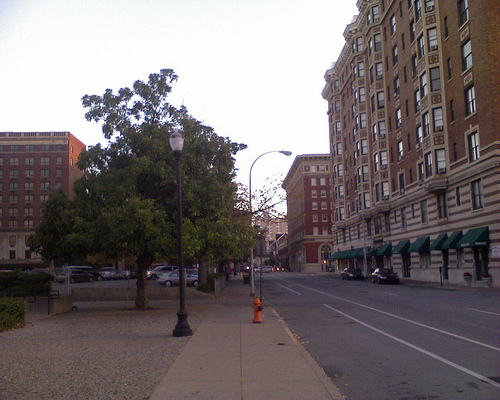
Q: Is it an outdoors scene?
A: Yes, it is outdoors.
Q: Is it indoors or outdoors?
A: It is outdoors.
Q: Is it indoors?
A: No, it is outdoors.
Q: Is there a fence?
A: No, there are no fences.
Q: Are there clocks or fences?
A: No, there are no fences or clocks.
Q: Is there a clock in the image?
A: No, there are no clocks.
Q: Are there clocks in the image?
A: No, there are no clocks.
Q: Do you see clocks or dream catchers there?
A: No, there are no clocks or dream catchers.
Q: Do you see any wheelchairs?
A: No, there are no wheelchairs.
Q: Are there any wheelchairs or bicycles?
A: No, there are no wheelchairs or bicycles.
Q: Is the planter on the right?
A: Yes, the planter is on the right of the image.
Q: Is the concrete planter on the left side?
A: No, the planter is on the right of the image.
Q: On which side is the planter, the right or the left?
A: The planter is on the right of the image.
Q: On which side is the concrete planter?
A: The planter is on the right of the image.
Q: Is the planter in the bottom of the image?
A: Yes, the planter is in the bottom of the image.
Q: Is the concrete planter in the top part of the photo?
A: No, the planter is in the bottom of the image.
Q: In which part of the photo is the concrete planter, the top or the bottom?
A: The planter is in the bottom of the image.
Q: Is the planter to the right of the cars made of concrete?
A: Yes, the planter is made of concrete.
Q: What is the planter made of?
A: The planter is made of concrete.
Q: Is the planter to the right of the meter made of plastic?
A: No, the planter is made of cement.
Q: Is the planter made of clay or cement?
A: The planter is made of cement.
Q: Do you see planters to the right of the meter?
A: Yes, there is a planter to the right of the meter.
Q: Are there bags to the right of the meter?
A: No, there is a planter to the right of the meter.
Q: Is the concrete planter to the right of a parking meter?
A: Yes, the planter is to the right of a parking meter.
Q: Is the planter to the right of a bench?
A: No, the planter is to the right of a parking meter.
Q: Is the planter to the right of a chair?
A: No, the planter is to the right of the car.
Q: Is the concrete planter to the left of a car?
A: No, the planter is to the right of a car.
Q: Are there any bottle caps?
A: No, there are no bottle caps.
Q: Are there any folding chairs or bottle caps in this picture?
A: No, there are no bottle caps or folding chairs.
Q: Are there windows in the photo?
A: Yes, there are windows.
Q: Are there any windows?
A: Yes, there are windows.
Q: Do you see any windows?
A: Yes, there are windows.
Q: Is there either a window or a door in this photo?
A: Yes, there are windows.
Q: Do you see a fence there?
A: No, there are no fences.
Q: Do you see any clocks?
A: No, there are no clocks.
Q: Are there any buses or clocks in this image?
A: No, there are no clocks or buses.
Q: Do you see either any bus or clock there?
A: No, there are no clocks or buses.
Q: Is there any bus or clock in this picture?
A: No, there are no clocks or buses.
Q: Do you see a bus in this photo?
A: No, there are no buses.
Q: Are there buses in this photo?
A: No, there are no buses.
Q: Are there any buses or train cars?
A: No, there are no buses or train cars.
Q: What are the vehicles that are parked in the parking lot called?
A: The vehicles are cars.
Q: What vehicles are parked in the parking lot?
A: The vehicles are cars.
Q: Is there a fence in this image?
A: No, there are no fences.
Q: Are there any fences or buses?
A: No, there are no fences or buses.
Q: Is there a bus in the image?
A: No, there are no buses.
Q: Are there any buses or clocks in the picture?
A: No, there are no buses or clocks.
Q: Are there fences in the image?
A: No, there are no fences.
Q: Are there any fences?
A: No, there are no fences.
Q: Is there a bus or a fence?
A: No, there are no fences or buses.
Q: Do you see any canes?
A: No, there are no canes.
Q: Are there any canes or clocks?
A: No, there are no canes or clocks.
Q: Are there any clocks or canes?
A: No, there are no canes or clocks.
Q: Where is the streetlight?
A: The streetlight is on the sidewalk.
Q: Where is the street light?
A: The streetlight is on the sidewalk.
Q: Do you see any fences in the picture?
A: No, there are no fences.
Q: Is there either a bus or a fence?
A: No, there are no fences or buses.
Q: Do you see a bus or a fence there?
A: No, there are no fences or buses.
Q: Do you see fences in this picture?
A: No, there are no fences.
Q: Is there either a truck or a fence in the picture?
A: No, there are no fences or trucks.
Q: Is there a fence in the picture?
A: No, there are no fences.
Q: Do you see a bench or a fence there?
A: No, there are no fences or benches.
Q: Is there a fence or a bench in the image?
A: No, there are no fences or benches.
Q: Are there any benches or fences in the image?
A: No, there are no fences or benches.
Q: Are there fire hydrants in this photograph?
A: Yes, there is a fire hydrant.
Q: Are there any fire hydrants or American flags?
A: Yes, there is a fire hydrant.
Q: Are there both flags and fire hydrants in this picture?
A: No, there is a fire hydrant but no flags.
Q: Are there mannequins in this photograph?
A: No, there are no mannequins.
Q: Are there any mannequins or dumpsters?
A: No, there are no mannequins or dumpsters.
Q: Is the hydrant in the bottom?
A: Yes, the hydrant is in the bottom of the image.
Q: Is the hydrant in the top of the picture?
A: No, the hydrant is in the bottom of the image.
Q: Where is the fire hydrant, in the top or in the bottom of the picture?
A: The fire hydrant is in the bottom of the image.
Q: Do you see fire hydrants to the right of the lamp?
A: Yes, there is a fire hydrant to the right of the lamp.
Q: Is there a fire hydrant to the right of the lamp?
A: Yes, there is a fire hydrant to the right of the lamp.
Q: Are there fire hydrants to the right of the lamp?
A: Yes, there is a fire hydrant to the right of the lamp.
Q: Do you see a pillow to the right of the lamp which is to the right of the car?
A: No, there is a fire hydrant to the right of the lamp.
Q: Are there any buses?
A: No, there are no buses.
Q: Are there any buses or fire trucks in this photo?
A: No, there are no buses or fire trucks.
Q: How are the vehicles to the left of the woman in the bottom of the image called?
A: The vehicles are cars.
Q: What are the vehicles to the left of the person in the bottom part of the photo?
A: The vehicles are cars.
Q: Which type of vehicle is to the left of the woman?
A: The vehicles are cars.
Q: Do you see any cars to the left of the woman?
A: Yes, there are cars to the left of the woman.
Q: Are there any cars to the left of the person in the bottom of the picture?
A: Yes, there are cars to the left of the woman.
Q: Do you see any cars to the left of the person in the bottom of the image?
A: Yes, there are cars to the left of the woman.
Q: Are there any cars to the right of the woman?
A: No, the cars are to the left of the woman.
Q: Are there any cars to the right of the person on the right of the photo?
A: No, the cars are to the left of the woman.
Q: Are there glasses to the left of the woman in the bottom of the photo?
A: No, there are cars to the left of the woman.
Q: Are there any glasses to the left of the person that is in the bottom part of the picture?
A: No, there are cars to the left of the woman.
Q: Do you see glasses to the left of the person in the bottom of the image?
A: No, there are cars to the left of the woman.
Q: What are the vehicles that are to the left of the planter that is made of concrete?
A: The vehicles are cars.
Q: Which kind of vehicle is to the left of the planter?
A: The vehicles are cars.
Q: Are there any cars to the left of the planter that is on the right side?
A: Yes, there are cars to the left of the planter.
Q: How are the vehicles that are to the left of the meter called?
A: The vehicles are cars.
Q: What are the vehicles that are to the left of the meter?
A: The vehicles are cars.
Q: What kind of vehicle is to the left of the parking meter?
A: The vehicles are cars.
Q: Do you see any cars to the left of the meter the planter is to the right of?
A: Yes, there are cars to the left of the meter.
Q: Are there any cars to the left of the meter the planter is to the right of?
A: Yes, there are cars to the left of the meter.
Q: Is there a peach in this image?
A: No, there are no peaches.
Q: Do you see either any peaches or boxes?
A: No, there are no peaches or boxes.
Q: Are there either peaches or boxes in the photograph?
A: No, there are no peaches or boxes.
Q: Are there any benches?
A: No, there are no benches.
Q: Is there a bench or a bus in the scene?
A: No, there are no benches or buses.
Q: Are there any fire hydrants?
A: Yes, there is a fire hydrant.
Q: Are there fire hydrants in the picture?
A: Yes, there is a fire hydrant.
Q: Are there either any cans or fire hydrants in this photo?
A: Yes, there is a fire hydrant.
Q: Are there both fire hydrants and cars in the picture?
A: Yes, there are both a fire hydrant and a car.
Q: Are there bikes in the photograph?
A: No, there are no bikes.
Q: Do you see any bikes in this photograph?
A: No, there are no bikes.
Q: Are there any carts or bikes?
A: No, there are no bikes or carts.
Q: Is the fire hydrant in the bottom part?
A: Yes, the fire hydrant is in the bottom of the image.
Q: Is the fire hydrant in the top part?
A: No, the fire hydrant is in the bottom of the image.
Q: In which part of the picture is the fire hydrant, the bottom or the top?
A: The fire hydrant is in the bottom of the image.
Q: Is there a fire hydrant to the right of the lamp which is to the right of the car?
A: Yes, there is a fire hydrant to the right of the lamp.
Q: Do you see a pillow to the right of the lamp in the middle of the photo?
A: No, there is a fire hydrant to the right of the lamp.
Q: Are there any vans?
A: No, there are no vans.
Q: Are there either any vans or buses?
A: No, there are no vans or buses.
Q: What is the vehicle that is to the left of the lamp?
A: The vehicle is a car.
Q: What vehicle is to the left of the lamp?
A: The vehicle is a car.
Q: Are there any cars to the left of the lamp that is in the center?
A: Yes, there is a car to the left of the lamp.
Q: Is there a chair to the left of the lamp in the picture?
A: No, there is a car to the left of the lamp.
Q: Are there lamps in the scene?
A: Yes, there is a lamp.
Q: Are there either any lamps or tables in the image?
A: Yes, there is a lamp.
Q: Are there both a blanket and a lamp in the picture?
A: No, there is a lamp but no blankets.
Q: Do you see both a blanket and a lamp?
A: No, there is a lamp but no blankets.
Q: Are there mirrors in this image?
A: No, there are no mirrors.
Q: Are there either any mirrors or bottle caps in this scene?
A: No, there are no mirrors or bottle caps.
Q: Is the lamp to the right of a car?
A: Yes, the lamp is to the right of a car.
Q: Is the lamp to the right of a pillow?
A: No, the lamp is to the right of a car.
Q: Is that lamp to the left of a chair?
A: No, the lamp is to the left of the fire hydrant.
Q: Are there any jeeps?
A: No, there are no jeeps.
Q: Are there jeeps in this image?
A: No, there are no jeeps.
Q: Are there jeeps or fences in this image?
A: No, there are no jeeps or fences.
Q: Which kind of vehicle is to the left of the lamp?
A: The vehicle is a car.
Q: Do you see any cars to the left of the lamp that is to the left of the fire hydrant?
A: Yes, there is a car to the left of the lamp.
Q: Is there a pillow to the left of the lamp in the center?
A: No, there is a car to the left of the lamp.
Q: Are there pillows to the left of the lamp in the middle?
A: No, there is a car to the left of the lamp.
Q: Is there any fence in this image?
A: No, there are no fences.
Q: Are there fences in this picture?
A: No, there are no fences.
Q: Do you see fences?
A: No, there are no fences.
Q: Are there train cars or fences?
A: No, there are no fences or train cars.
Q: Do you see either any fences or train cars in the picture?
A: No, there are no fences or train cars.